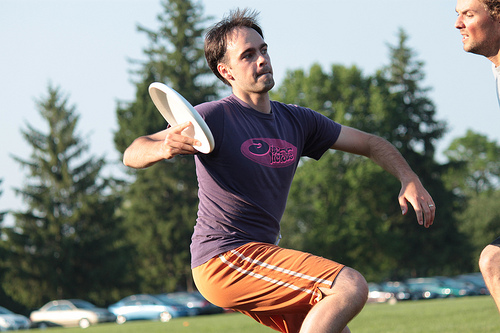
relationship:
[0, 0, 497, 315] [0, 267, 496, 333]
trees near car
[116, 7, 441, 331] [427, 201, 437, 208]
man with ring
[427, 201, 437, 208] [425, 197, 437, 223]
ring on finger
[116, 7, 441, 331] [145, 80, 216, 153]
man holds frisbee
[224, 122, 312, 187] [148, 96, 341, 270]
logo on purple shirt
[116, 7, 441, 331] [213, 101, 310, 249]
man with purple shirt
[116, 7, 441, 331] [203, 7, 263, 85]
man with hair